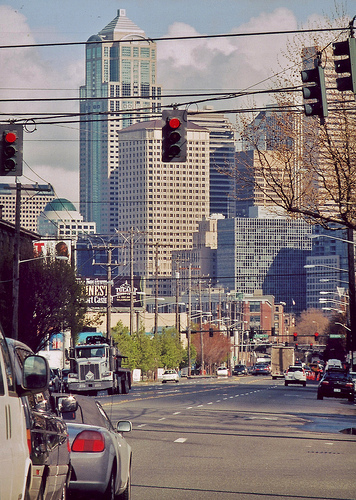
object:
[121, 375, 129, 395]
wheel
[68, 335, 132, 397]
truck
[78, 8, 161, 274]
building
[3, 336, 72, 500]
car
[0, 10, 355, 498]
city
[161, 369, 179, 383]
car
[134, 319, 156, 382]
trees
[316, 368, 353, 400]
black car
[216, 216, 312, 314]
building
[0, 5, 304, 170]
clouds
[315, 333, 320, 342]
traffic light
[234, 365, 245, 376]
car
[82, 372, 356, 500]
ground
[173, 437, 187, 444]
line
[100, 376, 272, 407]
line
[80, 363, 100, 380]
grill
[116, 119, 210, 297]
building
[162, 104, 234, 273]
building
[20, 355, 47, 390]
view mirrors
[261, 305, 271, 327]
brick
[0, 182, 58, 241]
building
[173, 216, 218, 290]
building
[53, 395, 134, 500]
car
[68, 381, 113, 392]
fender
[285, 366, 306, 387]
car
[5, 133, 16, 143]
red light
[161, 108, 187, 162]
light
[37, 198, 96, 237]
building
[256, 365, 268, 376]
car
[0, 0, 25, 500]
left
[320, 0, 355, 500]
right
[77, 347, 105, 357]
window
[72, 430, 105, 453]
light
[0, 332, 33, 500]
car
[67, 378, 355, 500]
road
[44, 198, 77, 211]
dome